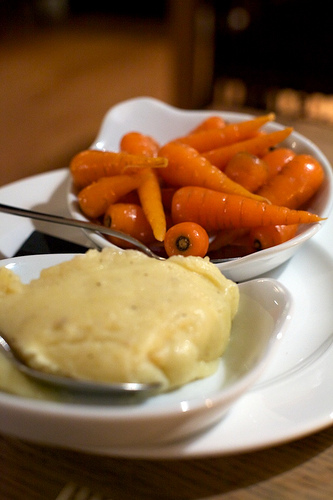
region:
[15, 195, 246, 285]
silver spoon in carrot dish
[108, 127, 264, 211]
Carrots in oval dish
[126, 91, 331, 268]
Oval dish is white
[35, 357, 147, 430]
Spoon in white dish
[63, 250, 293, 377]
Off white food in white dish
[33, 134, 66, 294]
Black napkin under dishes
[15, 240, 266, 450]
White dish on top of plate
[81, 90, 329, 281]
White oval dish on top of plate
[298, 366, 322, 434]
Plate is white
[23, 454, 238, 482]
Plate is on brown table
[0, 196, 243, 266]
The fork in the bowl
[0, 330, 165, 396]
Spoon in the bowl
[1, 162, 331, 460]
Plate that the bowls are on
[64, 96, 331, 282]
The bowl with the carrots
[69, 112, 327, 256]
The carrots in the bowl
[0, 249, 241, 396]
Yellow substance in a bowl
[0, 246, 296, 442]
Bowl with the yellow substance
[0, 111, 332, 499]
Table that the plate is on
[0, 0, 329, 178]
Out of focus background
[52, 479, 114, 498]
Fork mostly of screen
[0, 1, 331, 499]
A photograph of food.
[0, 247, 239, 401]
A spoon of mashed potatoes.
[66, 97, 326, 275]
A bowl of carrots.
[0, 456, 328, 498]
A dark wooden table.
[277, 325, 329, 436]
A white porcelain dish.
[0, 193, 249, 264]
A silver fork in the bowl.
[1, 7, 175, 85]
The blurred image of a hardwood floor.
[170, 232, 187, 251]
The end of the carrot.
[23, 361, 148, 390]
The silver spoon in the bowl.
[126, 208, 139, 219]
The shiny area of the carrots.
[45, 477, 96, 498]
fork is barely visible in image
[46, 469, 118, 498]
fork is barely visible in image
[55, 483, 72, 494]
fork is barely visible in image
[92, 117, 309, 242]
these are carrots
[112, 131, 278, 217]
the carrots are orange in color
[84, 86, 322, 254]
the carrots are on a bowl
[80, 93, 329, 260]
the bowl is white in color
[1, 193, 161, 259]
this is a spoon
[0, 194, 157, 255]
the spoon is shiny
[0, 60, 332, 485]
this is a plate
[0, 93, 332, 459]
the plate has two bowl on top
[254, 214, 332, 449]
the plate is white in color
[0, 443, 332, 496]
this is a table